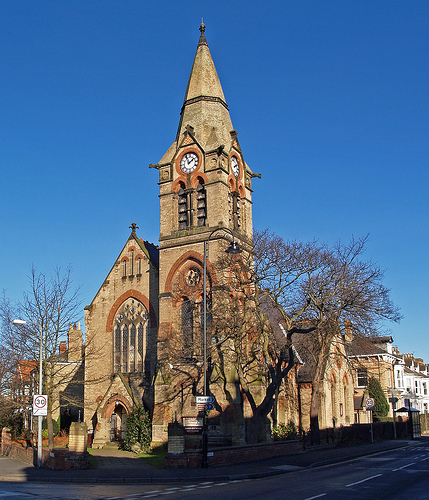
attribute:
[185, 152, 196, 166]
black hands — round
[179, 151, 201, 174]
clock face — white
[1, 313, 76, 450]
lamp — tall, metal, grey